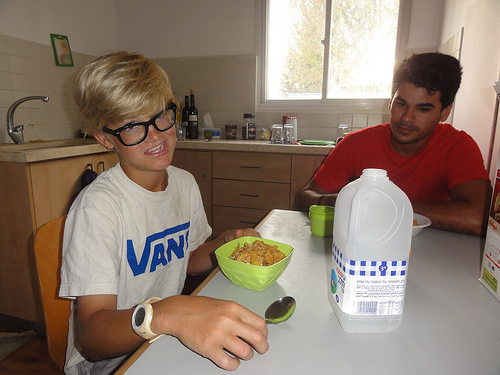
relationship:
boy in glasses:
[78, 64, 211, 364] [105, 115, 183, 133]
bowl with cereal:
[244, 264, 266, 285] [242, 247, 268, 256]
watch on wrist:
[129, 306, 167, 350] [158, 300, 187, 338]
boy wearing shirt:
[78, 64, 211, 364] [74, 171, 234, 288]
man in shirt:
[324, 48, 470, 248] [339, 112, 469, 210]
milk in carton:
[348, 240, 402, 247] [333, 176, 403, 345]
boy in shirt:
[78, 64, 211, 364] [74, 171, 234, 288]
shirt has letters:
[74, 171, 234, 288] [122, 238, 192, 274]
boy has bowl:
[78, 64, 211, 364] [244, 264, 266, 285]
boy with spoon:
[78, 64, 211, 364] [250, 302, 295, 327]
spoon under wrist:
[250, 302, 295, 327] [158, 300, 187, 338]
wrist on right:
[158, 300, 187, 338] [186, 298, 243, 367]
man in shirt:
[324, 48, 470, 248] [74, 171, 234, 288]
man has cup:
[324, 48, 470, 248] [311, 207, 337, 235]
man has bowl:
[324, 48, 470, 248] [244, 264, 266, 285]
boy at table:
[78, 64, 211, 364] [374, 341, 441, 367]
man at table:
[324, 48, 470, 248] [374, 341, 441, 367]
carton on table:
[333, 176, 403, 345] [374, 341, 441, 367]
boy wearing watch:
[78, 64, 211, 364] [129, 306, 167, 350]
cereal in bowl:
[242, 247, 268, 256] [244, 264, 266, 285]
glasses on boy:
[105, 115, 183, 133] [78, 64, 211, 364]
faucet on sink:
[1, 72, 54, 172] [10, 125, 57, 173]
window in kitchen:
[268, 8, 391, 96] [43, 99, 469, 343]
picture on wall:
[38, 33, 87, 73] [162, 39, 232, 55]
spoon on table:
[250, 302, 295, 327] [374, 341, 441, 367]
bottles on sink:
[178, 94, 204, 134] [10, 125, 57, 173]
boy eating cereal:
[78, 64, 211, 364] [242, 247, 268, 256]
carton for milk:
[333, 176, 403, 345] [348, 240, 402, 247]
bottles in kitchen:
[178, 94, 204, 134] [43, 99, 469, 343]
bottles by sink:
[178, 94, 204, 134] [10, 125, 57, 173]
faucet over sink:
[1, 72, 54, 172] [10, 125, 57, 173]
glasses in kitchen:
[278, 121, 318, 156] [43, 99, 469, 343]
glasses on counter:
[278, 121, 318, 156] [203, 144, 248, 154]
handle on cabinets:
[238, 191, 299, 196] [214, 152, 291, 219]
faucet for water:
[1, 72, 54, 172] [35, 120, 67, 153]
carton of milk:
[333, 176, 403, 345] [348, 240, 402, 247]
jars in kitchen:
[212, 111, 268, 125] [43, 99, 469, 343]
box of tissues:
[203, 132, 236, 140] [199, 102, 212, 125]